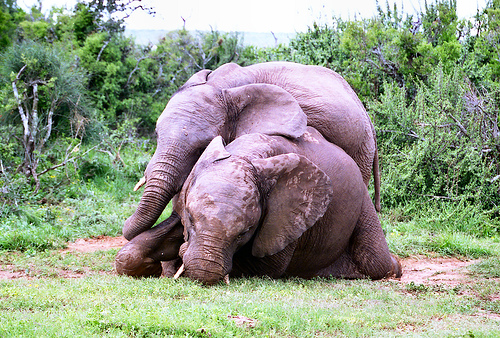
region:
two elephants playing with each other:
[104, 53, 403, 278]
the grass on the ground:
[8, 275, 496, 336]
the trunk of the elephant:
[126, 141, 194, 242]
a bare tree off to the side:
[12, 83, 57, 179]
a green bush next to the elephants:
[373, 73, 498, 197]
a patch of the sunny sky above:
[147, 2, 333, 33]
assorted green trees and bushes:
[22, 11, 494, 98]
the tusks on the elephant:
[166, 261, 239, 283]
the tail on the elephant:
[368, 155, 385, 210]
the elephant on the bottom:
[116, 139, 406, 286]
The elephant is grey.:
[145, 143, 397, 282]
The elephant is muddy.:
[126, 138, 383, 288]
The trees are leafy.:
[7, 3, 495, 123]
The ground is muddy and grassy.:
[15, 225, 499, 335]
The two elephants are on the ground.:
[120, 50, 403, 317]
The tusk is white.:
[127, 167, 152, 196]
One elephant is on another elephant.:
[109, 42, 414, 297]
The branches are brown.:
[7, 82, 52, 183]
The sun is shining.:
[1, 3, 489, 333]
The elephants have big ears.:
[100, 57, 416, 301]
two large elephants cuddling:
[115, 60, 400, 282]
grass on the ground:
[0, 275, 490, 335]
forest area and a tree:
[0, 0, 115, 265]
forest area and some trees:
[380, 0, 496, 280]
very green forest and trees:
[0, 0, 499, 60]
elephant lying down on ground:
[116, 126, 397, 276]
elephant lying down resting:
[136, 57, 386, 142]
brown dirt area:
[405, 256, 467, 281]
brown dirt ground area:
[70, 235, 120, 250]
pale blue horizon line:
[136, 2, 361, 47]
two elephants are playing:
[96, 43, 413, 295]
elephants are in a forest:
[0, 3, 497, 333]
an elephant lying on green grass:
[0, 123, 496, 334]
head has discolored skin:
[178, 148, 270, 244]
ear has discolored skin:
[251, 143, 342, 250]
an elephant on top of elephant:
[118, 38, 395, 193]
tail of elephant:
[369, 128, 387, 214]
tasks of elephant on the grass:
[158, 253, 245, 295]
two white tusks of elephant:
[161, 255, 240, 290]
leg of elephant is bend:
[102, 213, 181, 287]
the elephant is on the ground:
[172, 135, 350, 265]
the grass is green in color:
[264, 296, 326, 326]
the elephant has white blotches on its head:
[194, 148, 267, 258]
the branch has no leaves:
[462, 95, 496, 142]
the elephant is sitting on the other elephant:
[192, 55, 357, 154]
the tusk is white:
[171, 261, 193, 287]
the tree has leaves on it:
[423, 19, 463, 74]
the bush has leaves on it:
[67, 23, 116, 90]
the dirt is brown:
[410, 253, 447, 286]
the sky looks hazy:
[188, 3, 267, 26]